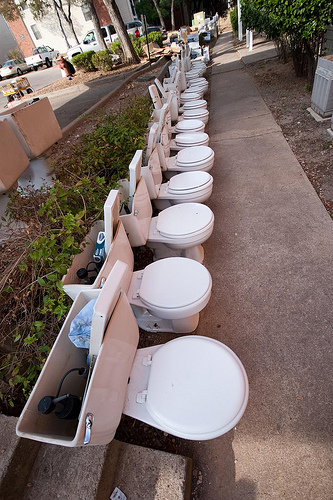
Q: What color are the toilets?
A: White.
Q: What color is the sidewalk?
A: Gray.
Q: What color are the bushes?
A: Green.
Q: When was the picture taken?
A: Daytime.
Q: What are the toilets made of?
A: Porcelain.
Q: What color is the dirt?
A: Brown.